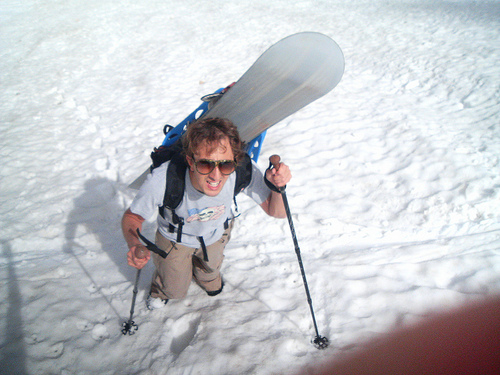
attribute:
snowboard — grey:
[230, 26, 344, 122]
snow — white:
[389, 42, 464, 147]